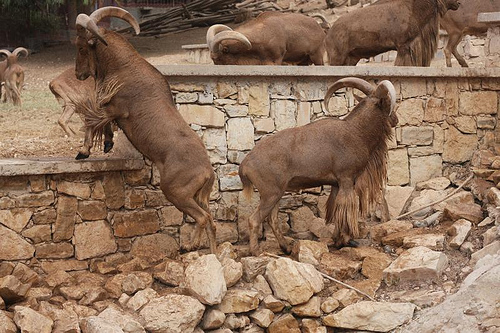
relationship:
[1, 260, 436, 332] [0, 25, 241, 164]
rocks on ground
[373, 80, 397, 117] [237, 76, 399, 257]
horn on ram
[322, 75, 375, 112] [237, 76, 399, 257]
horn on ram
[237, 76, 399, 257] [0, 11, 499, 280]
ram in wall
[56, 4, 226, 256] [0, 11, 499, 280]
ram in wall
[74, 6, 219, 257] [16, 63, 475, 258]
ram on wall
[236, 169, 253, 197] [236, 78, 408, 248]
brown tail on ram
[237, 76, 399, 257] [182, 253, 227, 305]
ram on large rock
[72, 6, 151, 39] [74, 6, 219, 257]
horns on ram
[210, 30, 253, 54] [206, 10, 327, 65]
horn on ram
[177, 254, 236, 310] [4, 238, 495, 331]
large rock on ground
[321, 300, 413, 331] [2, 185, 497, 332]
rock on ground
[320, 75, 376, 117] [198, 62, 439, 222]
horn on goat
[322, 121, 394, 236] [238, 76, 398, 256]
hair on goat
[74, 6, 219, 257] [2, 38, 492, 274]
ram on fence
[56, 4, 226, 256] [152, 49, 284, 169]
ram jumping on wall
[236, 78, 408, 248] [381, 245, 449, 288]
ram walking on large rock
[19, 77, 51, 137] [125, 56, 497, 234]
dirt behind wall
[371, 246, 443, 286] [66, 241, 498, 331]
large rock on ground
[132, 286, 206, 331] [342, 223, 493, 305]
rock on ground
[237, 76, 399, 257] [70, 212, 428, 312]
ram on rock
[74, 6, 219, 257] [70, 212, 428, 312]
ram on rock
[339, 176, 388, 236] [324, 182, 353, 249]
hair on leg